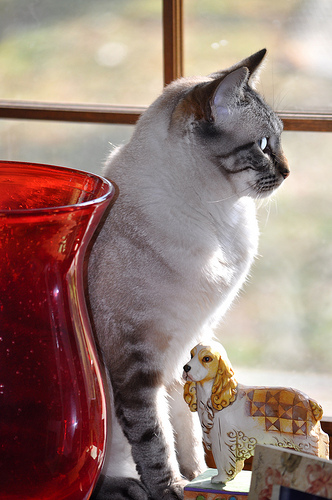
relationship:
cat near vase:
[95, 47, 309, 491] [0, 154, 121, 499]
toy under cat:
[173, 343, 331, 481] [95, 47, 309, 491]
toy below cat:
[173, 343, 331, 481] [95, 47, 309, 491]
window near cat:
[1, 3, 331, 452] [95, 47, 309, 491]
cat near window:
[95, 47, 309, 491] [1, 3, 331, 452]